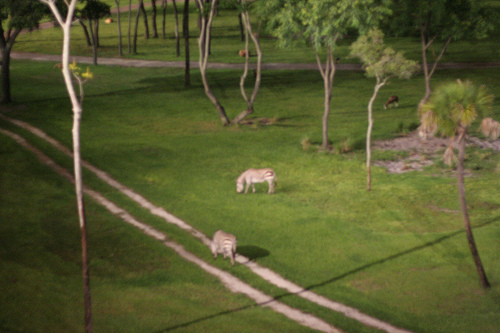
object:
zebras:
[206, 230, 237, 263]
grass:
[0, 0, 497, 333]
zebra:
[234, 167, 277, 196]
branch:
[430, 34, 454, 77]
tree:
[408, 0, 491, 109]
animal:
[382, 93, 400, 108]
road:
[6, 49, 498, 75]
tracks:
[0, 114, 411, 333]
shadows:
[34, 62, 347, 103]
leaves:
[396, 3, 489, 39]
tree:
[416, 80, 499, 308]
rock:
[101, 12, 115, 26]